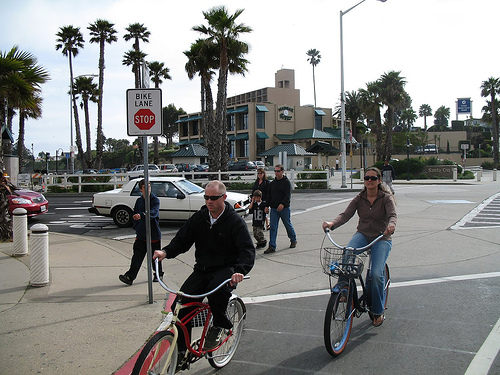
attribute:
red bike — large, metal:
[127, 246, 251, 373]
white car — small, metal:
[92, 171, 257, 235]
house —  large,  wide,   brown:
[179, 68, 375, 188]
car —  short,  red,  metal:
[1, 186, 57, 224]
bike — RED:
[126, 250, 253, 360]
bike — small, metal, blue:
[315, 229, 396, 356]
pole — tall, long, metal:
[135, 136, 159, 316]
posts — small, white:
[13, 203, 48, 290]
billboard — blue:
[451, 93, 478, 120]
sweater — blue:
[131, 196, 160, 241]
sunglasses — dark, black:
[360, 169, 385, 183]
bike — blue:
[312, 220, 398, 361]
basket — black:
[318, 236, 378, 279]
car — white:
[92, 171, 246, 231]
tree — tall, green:
[352, 66, 412, 144]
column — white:
[27, 218, 69, 292]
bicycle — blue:
[320, 223, 392, 353]